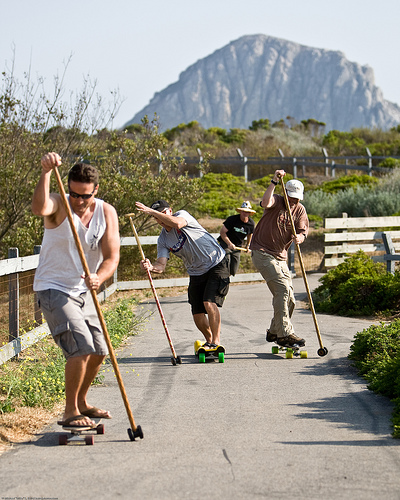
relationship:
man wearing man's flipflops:
[38, 160, 119, 427] [56, 414, 96, 428]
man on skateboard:
[38, 160, 119, 427] [53, 407, 105, 443]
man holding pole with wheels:
[38, 150, 119, 427] [47, 151, 148, 440]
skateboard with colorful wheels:
[187, 341, 226, 365] [57, 424, 105, 445]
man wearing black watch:
[253, 169, 311, 346] [269, 176, 279, 187]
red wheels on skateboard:
[60, 425, 106, 444] [59, 407, 103, 443]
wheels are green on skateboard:
[195, 350, 225, 364] [191, 336, 225, 361]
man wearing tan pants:
[253, 169, 311, 346] [250, 246, 298, 335]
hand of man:
[270, 168, 286, 186] [253, 169, 311, 346]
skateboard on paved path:
[58, 408, 103, 446] [0, 272, 398, 499]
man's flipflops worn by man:
[56, 414, 96, 428] [38, 160, 119, 427]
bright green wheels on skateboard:
[268, 342, 306, 361] [187, 338, 229, 363]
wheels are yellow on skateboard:
[283, 348, 311, 359] [265, 333, 307, 361]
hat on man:
[281, 177, 305, 200] [253, 169, 311, 346]